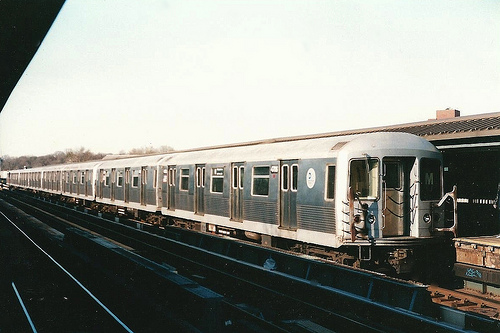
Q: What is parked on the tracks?
A: Long train.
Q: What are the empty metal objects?
A: Train tracks.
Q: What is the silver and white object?
A: Train.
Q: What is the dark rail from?
A: Train.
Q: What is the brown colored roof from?
A: Train station.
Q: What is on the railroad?
A: Train.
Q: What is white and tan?
A: Train.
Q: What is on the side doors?
A: Two windows.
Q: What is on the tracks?
A: Train.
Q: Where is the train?
A: Station.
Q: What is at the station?
A: Train.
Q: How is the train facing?
A: To the right.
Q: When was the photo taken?
A: Morning.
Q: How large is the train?
A: Very large.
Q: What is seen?
A: Train.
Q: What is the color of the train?
A: Grey.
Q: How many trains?
A: 1.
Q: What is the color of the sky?
A: Blue.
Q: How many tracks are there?
A: 2.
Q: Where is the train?
A: In the track.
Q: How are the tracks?
A: Parallel to each other.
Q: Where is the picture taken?
A: At a train station.